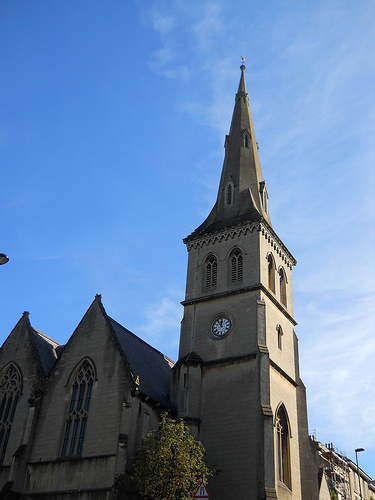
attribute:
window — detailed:
[2, 358, 27, 460]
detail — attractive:
[124, 385, 172, 443]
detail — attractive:
[94, 291, 104, 303]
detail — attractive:
[8, 392, 46, 494]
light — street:
[353, 445, 367, 498]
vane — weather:
[239, 53, 245, 68]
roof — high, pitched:
[99, 307, 174, 410]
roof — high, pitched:
[26, 317, 63, 382]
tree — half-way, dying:
[111, 410, 222, 497]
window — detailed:
[52, 354, 101, 459]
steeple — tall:
[176, 55, 317, 498]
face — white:
[212, 315, 229, 336]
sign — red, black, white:
[190, 479, 213, 498]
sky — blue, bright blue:
[4, 4, 374, 476]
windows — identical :
[198, 241, 249, 294]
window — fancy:
[53, 350, 106, 461]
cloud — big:
[299, 243, 366, 441]